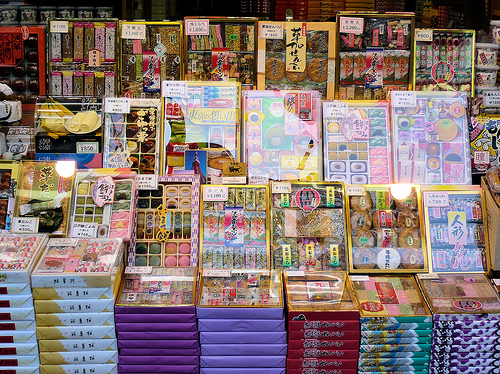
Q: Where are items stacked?
A: Front of display.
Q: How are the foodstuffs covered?
A: Transparent material.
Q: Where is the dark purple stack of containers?
A: Third stack from left.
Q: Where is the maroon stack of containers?
A: Fifth stack from left.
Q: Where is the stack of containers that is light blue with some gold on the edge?
A: Second stack from left.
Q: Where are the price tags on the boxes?
A: Upper left on each box.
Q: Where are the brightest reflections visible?
A: Packages in second row of standing packages.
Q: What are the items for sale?
A: Candy.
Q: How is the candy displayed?
A: The candy is stacked.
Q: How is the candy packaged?
A: In plastic.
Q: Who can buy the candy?
A: A customer.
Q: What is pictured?
A: Food.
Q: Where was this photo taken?
A: Market.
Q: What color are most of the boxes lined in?
A: Gold.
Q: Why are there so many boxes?
A: For sale.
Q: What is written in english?
A: Nothing.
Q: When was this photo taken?
A: Daytime.